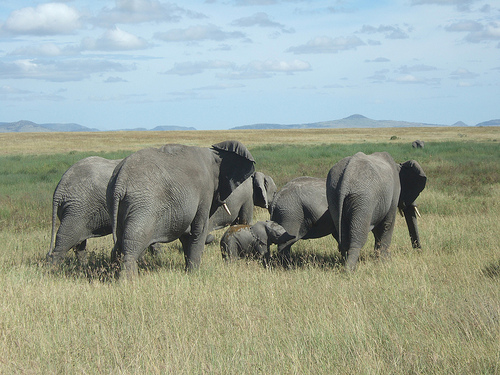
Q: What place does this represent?
A: It represents the plain.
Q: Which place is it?
A: It is a plain.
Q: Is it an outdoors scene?
A: Yes, it is outdoors.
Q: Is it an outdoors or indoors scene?
A: It is outdoors.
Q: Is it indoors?
A: No, it is outdoors.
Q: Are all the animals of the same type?
A: Yes, all the animals are elephants.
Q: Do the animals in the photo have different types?
A: No, all the animals are elephants.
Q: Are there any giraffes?
A: No, there are no giraffes.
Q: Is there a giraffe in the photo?
A: No, there are no giraffes.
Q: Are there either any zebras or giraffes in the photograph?
A: No, there are no giraffes or zebras.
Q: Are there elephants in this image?
A: Yes, there is an elephant.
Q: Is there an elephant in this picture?
A: Yes, there is an elephant.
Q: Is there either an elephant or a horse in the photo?
A: Yes, there is an elephant.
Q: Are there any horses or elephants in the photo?
A: Yes, there is an elephant.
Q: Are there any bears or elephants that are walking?
A: Yes, the elephant is walking.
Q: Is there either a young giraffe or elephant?
A: Yes, there is a young elephant.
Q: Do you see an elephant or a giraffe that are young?
A: Yes, the elephant is young.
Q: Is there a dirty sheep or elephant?
A: Yes, there is a dirty elephant.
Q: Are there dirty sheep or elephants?
A: Yes, there is a dirty elephant.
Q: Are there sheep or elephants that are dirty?
A: Yes, the elephant is dirty.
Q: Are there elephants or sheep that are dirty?
A: Yes, the elephant is dirty.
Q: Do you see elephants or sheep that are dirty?
A: Yes, the elephant is dirty.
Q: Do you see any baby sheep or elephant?
A: Yes, there is a baby elephant.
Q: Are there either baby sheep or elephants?
A: Yes, there is a baby elephant.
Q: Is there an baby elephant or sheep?
A: Yes, there is a baby elephant.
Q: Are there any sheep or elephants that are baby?
A: Yes, the elephant is a baby.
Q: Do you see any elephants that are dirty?
A: Yes, there is a dirty elephant.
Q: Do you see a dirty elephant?
A: Yes, there is a dirty elephant.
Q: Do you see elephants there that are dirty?
A: Yes, there is an elephant that is dirty.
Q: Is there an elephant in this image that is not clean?
A: Yes, there is a dirty elephant.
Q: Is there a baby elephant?
A: Yes, there is a baby elephant.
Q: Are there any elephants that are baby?
A: Yes, there is an elephant that is a baby.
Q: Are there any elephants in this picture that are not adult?
A: Yes, there is an baby elephant.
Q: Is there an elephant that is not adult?
A: Yes, there is an baby elephant.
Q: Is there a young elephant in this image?
A: Yes, there is a young elephant.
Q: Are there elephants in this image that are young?
A: Yes, there is an elephant that is young.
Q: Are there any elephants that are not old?
A: Yes, there is an young elephant.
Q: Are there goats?
A: No, there are no goats.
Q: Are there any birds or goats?
A: No, there are no goats or birds.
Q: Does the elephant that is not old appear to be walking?
A: Yes, the elephant is walking.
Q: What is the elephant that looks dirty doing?
A: The elephant is walking.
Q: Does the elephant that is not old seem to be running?
A: No, the elephant is walking.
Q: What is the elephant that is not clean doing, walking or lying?
A: The elephant is walking.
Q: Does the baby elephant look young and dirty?
A: Yes, the elephant is young and dirty.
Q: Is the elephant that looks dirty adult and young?
A: No, the elephant is young but baby.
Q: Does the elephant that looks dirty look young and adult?
A: No, the elephant is young but baby.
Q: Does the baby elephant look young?
A: Yes, the elephant is young.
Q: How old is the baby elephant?
A: The elephant is young.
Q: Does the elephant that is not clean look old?
A: No, the elephant is young.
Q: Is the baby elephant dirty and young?
A: Yes, the elephant is dirty and young.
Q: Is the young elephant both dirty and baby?
A: Yes, the elephant is dirty and baby.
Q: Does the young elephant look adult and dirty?
A: No, the elephant is dirty but baby.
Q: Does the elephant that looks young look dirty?
A: Yes, the elephant is dirty.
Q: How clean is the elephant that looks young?
A: The elephant is dirty.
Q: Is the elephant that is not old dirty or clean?
A: The elephant is dirty.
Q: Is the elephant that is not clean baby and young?
A: Yes, the elephant is a baby and young.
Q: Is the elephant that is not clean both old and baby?
A: No, the elephant is a baby but young.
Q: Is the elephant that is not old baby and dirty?
A: Yes, the elephant is a baby and dirty.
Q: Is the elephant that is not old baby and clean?
A: No, the elephant is a baby but dirty.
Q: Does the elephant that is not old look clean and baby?
A: No, the elephant is a baby but dirty.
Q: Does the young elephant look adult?
A: No, the elephant is a baby.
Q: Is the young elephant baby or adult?
A: The elephant is a baby.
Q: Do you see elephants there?
A: Yes, there is an elephant.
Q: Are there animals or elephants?
A: Yes, there is an elephant.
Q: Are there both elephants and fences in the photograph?
A: No, there is an elephant but no fences.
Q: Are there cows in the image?
A: No, there are no cows.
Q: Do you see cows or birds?
A: No, there are no cows or birds.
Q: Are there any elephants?
A: Yes, there are elephants.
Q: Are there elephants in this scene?
A: Yes, there are elephants.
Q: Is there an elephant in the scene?
A: Yes, there are elephants.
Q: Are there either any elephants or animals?
A: Yes, there are elephants.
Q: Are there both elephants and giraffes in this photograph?
A: No, there are elephants but no giraffes.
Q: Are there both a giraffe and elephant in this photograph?
A: No, there are elephants but no giraffes.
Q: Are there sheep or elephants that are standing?
A: Yes, the elephants are standing.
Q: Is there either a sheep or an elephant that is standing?
A: Yes, the elephants are standing.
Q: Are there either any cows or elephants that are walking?
A: Yes, the elephants are walking.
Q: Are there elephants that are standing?
A: Yes, there are elephants that are standing.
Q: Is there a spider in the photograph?
A: No, there are no spiders.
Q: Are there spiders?
A: No, there are no spiders.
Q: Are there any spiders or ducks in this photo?
A: No, there are no spiders or ducks.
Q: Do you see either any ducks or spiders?
A: No, there are no spiders or ducks.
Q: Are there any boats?
A: No, there are no boats.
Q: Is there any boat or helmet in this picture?
A: No, there are no boats or helmets.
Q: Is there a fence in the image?
A: No, there are no fences.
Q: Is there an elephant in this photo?
A: Yes, there is an elephant.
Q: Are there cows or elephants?
A: Yes, there is an elephant.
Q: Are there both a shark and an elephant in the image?
A: No, there is an elephant but no sharks.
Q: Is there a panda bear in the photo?
A: No, there are no pandas.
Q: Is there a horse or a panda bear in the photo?
A: No, there are no pandas or horses.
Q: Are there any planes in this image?
A: No, there are no planes.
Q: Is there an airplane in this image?
A: No, there are no airplanes.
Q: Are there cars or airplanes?
A: No, there are no airplanes or cars.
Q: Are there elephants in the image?
A: Yes, there is an elephant.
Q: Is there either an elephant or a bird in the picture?
A: Yes, there is an elephant.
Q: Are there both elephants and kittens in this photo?
A: No, there is an elephant but no kittens.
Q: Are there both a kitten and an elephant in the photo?
A: No, there is an elephant but no kittens.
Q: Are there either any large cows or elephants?
A: Yes, there is a large elephant.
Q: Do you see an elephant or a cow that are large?
A: Yes, the elephant is large.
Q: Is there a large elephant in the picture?
A: Yes, there is a large elephant.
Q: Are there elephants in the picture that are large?
A: Yes, there is an elephant that is large.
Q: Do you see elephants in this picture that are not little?
A: Yes, there is a large elephant.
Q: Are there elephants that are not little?
A: Yes, there is a large elephant.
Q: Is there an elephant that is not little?
A: Yes, there is a large elephant.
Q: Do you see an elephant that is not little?
A: Yes, there is a large elephant.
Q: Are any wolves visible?
A: No, there are no wolves.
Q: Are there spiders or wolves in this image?
A: No, there are no wolves or spiders.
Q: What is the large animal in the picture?
A: The animal is an elephant.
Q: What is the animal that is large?
A: The animal is an elephant.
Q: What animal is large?
A: The animal is an elephant.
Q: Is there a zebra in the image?
A: No, there are no zebras.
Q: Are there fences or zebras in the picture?
A: No, there are no zebras or fences.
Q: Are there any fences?
A: No, there are no fences.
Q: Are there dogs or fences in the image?
A: No, there are no fences or dogs.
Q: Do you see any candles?
A: No, there are no candles.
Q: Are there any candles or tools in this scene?
A: No, there are no candles or tools.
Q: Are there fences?
A: No, there are no fences.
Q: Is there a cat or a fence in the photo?
A: No, there are no fences or cats.